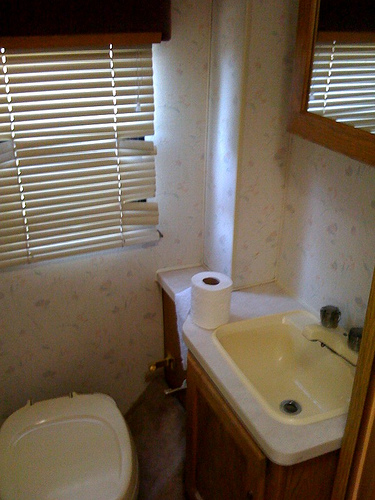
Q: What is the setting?
A: A bathroom.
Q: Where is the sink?
A: In the counter.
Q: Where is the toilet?
A: Near the sink.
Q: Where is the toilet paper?
A: On the counter.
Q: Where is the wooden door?
A: Under the sink.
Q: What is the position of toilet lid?
A: Up.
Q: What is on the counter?
A: A roll of toilet paper.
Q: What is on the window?
A: Mini blinds.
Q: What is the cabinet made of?
A: Wood.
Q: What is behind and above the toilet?
A: A window.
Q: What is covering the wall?
A: Flowery wallpaper.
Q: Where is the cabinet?
A: Under the sink.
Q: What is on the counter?
A: Toilet paper.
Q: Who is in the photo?
A: Nobody.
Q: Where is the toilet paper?
A: On the counter.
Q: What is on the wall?
A: A mirror.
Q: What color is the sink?
A: White.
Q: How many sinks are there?
A: One.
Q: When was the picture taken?
A: Daytime.